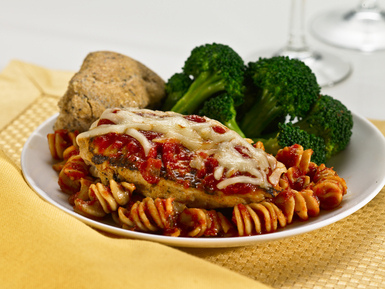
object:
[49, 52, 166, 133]
bread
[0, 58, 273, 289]
placemat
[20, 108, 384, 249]
plate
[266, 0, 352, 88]
wineglass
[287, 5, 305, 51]
stem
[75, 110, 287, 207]
chicken breast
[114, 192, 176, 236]
pasta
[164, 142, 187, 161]
sauce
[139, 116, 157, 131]
cheese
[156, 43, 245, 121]
broccoli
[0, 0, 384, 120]
table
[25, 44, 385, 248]
dinner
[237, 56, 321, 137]
vegetable